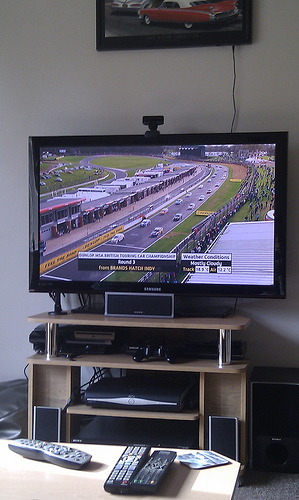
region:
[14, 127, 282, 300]
black frame on television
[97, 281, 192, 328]
speaker is under television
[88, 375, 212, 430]
cable box under television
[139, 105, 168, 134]
camera on top of television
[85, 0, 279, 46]
picture of car above television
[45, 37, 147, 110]
white wall under picture frame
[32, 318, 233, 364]
game systems under television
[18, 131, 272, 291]
television on brown entertainment center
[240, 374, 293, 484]
speakers on grey carpet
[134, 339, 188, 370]
game controller above cable box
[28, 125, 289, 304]
a black slat screen tv on a stand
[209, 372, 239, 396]
tan wood surface of the entertainment center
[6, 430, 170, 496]
three black remote controls on a table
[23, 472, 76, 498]
tan wood surface of the coffee table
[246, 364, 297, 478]
a black speaker on the floor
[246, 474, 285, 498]
grey carpet of the floor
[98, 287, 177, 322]
a grey speaker on top of the enetertainment center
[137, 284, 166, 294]
white logo on the black tv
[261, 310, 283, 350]
white surface of the wall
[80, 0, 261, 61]
a framed poster hung on the wall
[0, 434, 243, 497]
remotes on table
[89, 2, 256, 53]
picture with red car in it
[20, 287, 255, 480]
sony speaker on tv stand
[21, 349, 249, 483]
wood color tv stand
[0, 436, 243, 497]
wood color center table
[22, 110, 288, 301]
game on television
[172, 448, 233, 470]
coaster on table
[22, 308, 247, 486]
game remote on stand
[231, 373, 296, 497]
speaker on floor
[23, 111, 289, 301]
camera on top of tv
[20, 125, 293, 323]
television in the room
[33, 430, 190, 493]
remotes on the table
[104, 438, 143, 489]
buttons on the remote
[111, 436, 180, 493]
two black remotes in the photo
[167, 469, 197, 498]
shadow next to remote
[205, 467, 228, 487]
light on the table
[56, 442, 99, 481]
head of the remote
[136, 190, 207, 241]
cars on the road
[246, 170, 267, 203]
people in the grass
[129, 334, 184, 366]
remote on the wood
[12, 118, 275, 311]
a flat screen tv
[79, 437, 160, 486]
a remote on a table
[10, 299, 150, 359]
a ps3 on a tv stand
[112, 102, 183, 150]
a small camera on top of a tv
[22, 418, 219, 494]
three remotes on a table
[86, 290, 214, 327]
a speaker on a tv stand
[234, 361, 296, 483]
a speaker on the floor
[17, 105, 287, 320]
a tv with race cars on it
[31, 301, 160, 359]
a black playstation three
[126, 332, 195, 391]
a ps3 controller on a tv stand